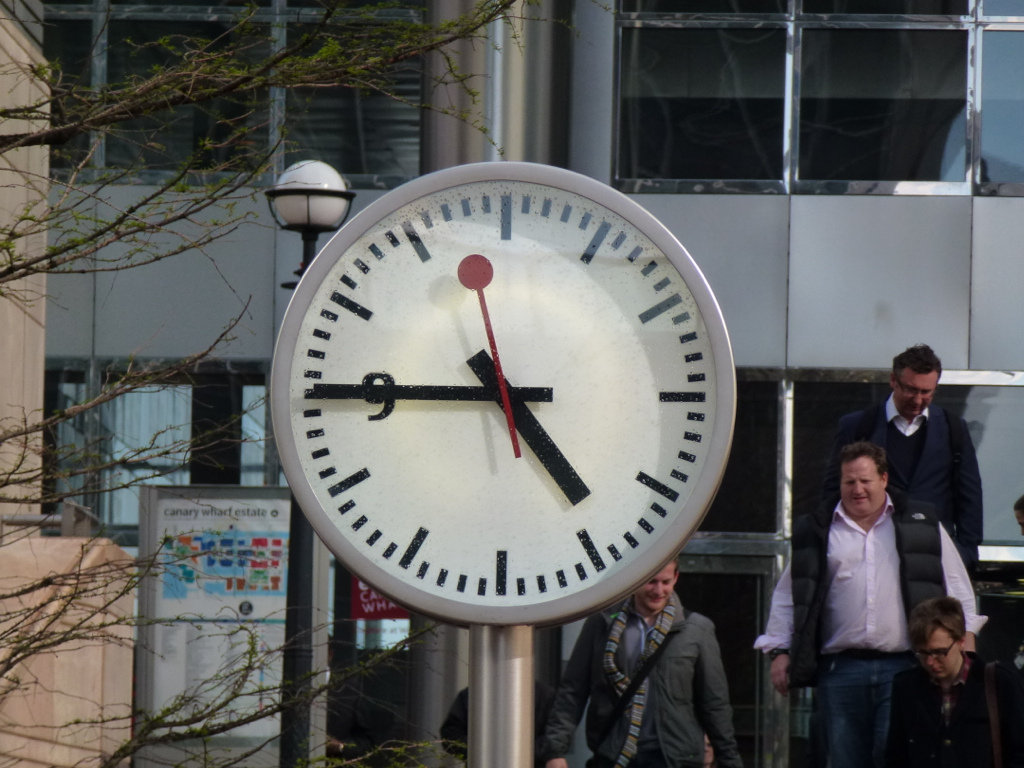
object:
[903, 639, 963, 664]
glasses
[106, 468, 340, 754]
sign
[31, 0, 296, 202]
window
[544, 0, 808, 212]
window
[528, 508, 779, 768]
window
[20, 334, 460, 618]
window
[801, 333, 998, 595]
person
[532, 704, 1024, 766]
sidewalk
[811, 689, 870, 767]
leg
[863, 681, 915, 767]
leg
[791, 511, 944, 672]
torso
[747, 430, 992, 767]
man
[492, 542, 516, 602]
6 position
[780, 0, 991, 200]
window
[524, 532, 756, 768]
man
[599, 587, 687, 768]
scarf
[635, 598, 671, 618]
neck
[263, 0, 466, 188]
window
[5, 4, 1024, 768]
building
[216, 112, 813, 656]
clock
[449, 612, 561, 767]
pole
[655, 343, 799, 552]
window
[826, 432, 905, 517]
head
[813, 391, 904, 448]
shoulders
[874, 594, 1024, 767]
person